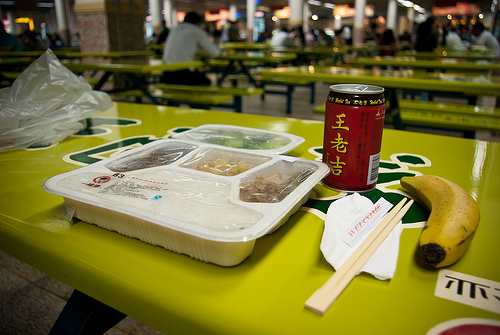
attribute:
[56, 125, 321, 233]
dinner — frozen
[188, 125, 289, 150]
side dish — frozen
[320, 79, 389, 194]
can — red, black, red+black, soda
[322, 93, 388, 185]
writing — yellow, chinese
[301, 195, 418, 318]
chopsticks — unwrapped, intact, wooden, wood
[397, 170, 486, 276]
banana — ripe, unpeeled, yellow, yellow+brown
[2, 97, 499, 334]
table — restaurant table, lime green, cafeteria table, bright, bright green, yellow, green, red, yellow+green+red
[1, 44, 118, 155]
bag — plastic, clear, clear plastic, empty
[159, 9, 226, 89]
man — eating alone, sitting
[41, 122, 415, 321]
package — white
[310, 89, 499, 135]
bench — green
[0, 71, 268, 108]
bench — green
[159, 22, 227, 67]
shirt — white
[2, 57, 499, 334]
floor — tiled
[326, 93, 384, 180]
writing on can — in chinese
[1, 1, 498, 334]
scene — in daytime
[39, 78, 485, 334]
food — lunch, sitting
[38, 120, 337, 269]
container — white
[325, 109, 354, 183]
chinese characters — golden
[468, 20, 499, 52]
man — sitting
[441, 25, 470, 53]
man — sitting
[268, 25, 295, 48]
man — sitting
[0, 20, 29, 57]
man — sitting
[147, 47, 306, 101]
table — green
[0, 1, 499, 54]
group — blurry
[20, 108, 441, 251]
writing — green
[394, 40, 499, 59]
tables — green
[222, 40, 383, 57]
tables — green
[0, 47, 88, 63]
tables — green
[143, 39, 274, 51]
tables — green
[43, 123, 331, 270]
compartments — separate